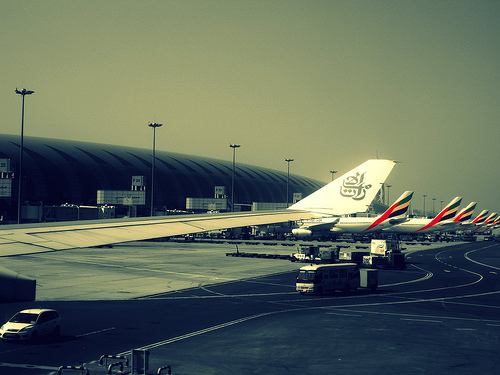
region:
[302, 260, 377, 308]
large bus for passengers by bus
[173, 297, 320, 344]
white lines on tarmac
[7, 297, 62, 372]
white car on left of photo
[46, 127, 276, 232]
dark airport in back of photo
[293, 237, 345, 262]
luggage transporters at airport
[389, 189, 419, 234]
striped tail wing of plane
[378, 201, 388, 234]
red stripe on plane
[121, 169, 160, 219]
airplane gate at airport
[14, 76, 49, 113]
light on the upper left of photo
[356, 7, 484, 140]
greenish grey sky in upper right of photo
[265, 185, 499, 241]
THE PLANES ARE PARKED IN A LINE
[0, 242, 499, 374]
THE LINES ARE PAINTED ON THE PAVEMENT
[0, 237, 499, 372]
THE LINES ON THE PAVEMENT ARE WHITE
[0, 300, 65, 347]
THE VAN IS WHITE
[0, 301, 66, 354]
THE VAN IS PARKED UNDER THE WING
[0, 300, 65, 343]
THE VAN IS PARKED ON THE TARMAC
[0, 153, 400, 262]
THE WING IS WHITE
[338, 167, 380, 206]
THE LOGO IS ON THE WING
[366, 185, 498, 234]
THE PLANES HAVE COLORFUL TAILS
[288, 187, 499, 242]
THE PLANES ARE WHITE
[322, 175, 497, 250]
row of planes on the tarmac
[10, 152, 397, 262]
long and thin airplane wing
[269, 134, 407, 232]
end of the wing is bent upwards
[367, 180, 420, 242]
red, green, yellow, and blue design on the tail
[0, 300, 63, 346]
white car on the tarmac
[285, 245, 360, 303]
bus on the tarmac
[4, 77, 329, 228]
row of light poles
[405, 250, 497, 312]
lines painted on the ground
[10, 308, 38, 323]
windshield of the car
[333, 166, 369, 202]
design on the wing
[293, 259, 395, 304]
A bus on the airport runway.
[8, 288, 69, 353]
A car driving on the airport runway.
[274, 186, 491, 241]
Airplanes lined up in a row.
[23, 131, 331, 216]
Part of the airport terminal.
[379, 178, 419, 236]
The tail on the plane is colorful.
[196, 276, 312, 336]
White lines on the runway.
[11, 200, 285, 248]
The wing of a plane.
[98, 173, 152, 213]
Terminal walkway attached to the airport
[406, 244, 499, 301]
The white lines are curvy.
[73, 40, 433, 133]
The sky is overcasted.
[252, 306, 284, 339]
part of a runway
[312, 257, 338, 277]
edge of a bus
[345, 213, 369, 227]
part of a plane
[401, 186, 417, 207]
edge of a wing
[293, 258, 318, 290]
part of a window